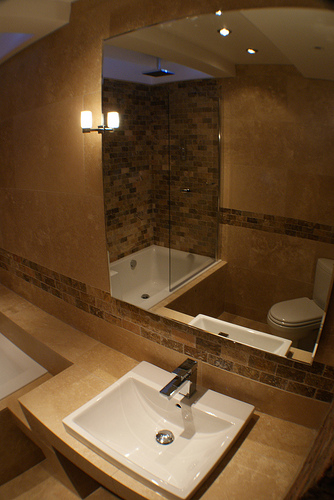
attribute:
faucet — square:
[153, 356, 199, 411]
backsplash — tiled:
[0, 248, 333, 404]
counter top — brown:
[0, 284, 320, 498]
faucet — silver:
[158, 356, 199, 399]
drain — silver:
[154, 428, 174, 445]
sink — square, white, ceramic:
[61, 352, 262, 498]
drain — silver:
[150, 418, 167, 451]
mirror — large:
[100, 7, 333, 366]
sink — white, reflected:
[181, 303, 329, 374]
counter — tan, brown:
[13, 338, 318, 498]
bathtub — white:
[0, 330, 50, 401]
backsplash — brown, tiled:
[104, 303, 284, 388]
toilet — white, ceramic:
[268, 257, 332, 340]